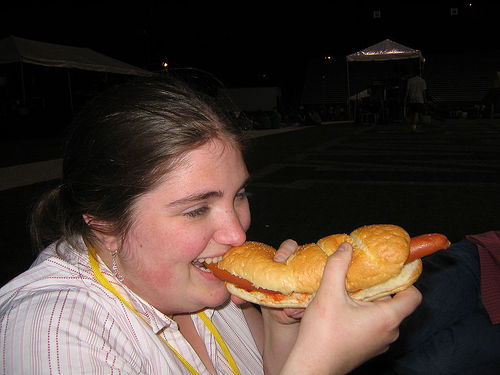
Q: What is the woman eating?
A: A hot dog.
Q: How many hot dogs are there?
A: One.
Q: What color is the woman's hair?
A: Brown.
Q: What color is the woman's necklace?
A: Yellow.